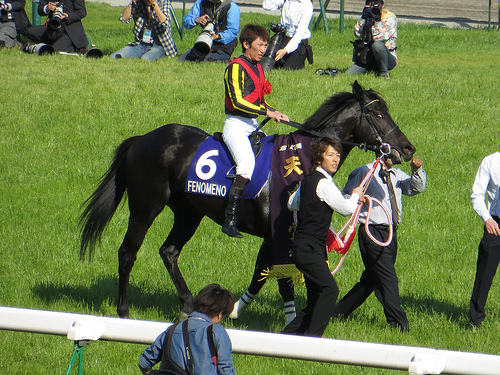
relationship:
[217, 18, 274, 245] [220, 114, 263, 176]
jockey wearing pants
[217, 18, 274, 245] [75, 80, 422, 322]
jockey on horse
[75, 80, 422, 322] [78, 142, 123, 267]
horse has tail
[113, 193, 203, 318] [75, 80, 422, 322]
legs of horse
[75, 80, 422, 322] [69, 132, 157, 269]
horse has tail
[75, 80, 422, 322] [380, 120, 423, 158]
horse has nose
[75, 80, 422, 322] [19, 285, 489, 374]
horse in grass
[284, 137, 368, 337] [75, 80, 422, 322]
man guiding horse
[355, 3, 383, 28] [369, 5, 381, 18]
camera with lens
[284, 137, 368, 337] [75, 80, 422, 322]
man leading a horse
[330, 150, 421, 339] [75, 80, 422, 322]
man leading a horse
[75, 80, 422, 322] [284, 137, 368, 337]
horse leading a man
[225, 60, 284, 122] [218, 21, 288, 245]
arm of man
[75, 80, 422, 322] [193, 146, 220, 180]
horse wears number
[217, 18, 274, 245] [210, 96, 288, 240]
jockey wearing pants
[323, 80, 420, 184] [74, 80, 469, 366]
head of horse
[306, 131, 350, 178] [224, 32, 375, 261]
head of lady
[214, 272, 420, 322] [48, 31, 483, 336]
shadow on ground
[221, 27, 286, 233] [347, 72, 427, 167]
rider on horse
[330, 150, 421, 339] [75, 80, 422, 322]
man guiding horse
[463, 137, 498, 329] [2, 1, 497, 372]
man standing on field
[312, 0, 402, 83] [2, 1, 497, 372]
photographer on field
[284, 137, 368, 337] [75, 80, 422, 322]
man walks with horse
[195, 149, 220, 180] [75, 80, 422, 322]
number shown on horse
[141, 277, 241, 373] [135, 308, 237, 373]
man wearing shirt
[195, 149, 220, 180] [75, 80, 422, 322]
number draped over horse